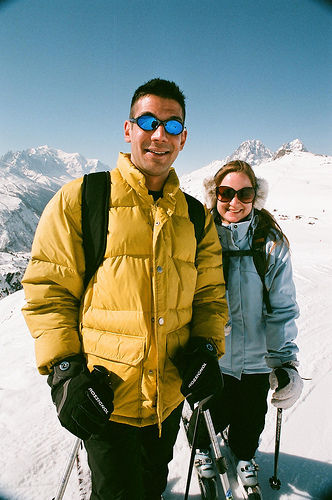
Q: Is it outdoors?
A: Yes, it is outdoors.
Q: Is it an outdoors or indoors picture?
A: It is outdoors.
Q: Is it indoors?
A: No, it is outdoors.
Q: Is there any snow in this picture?
A: Yes, there is snow.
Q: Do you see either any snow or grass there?
A: Yes, there is snow.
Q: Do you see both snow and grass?
A: No, there is snow but no grass.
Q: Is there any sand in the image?
A: No, there is no sand.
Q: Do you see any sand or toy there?
A: No, there are no sand or toys.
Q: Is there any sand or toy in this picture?
A: No, there are no sand or toys.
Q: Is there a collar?
A: Yes, there is a collar.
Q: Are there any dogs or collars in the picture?
A: Yes, there is a collar.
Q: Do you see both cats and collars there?
A: No, there is a collar but no cats.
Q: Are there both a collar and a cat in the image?
A: No, there is a collar but no cats.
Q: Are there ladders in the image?
A: No, there are no ladders.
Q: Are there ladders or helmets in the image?
A: No, there are no ladders or helmets.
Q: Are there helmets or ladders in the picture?
A: No, there are no ladders or helmets.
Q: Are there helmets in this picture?
A: No, there are no helmets.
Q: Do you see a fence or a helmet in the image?
A: No, there are no helmets or fences.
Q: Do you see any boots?
A: Yes, there are boots.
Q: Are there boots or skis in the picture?
A: Yes, there are boots.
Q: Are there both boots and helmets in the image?
A: No, there are boots but no helmets.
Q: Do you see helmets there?
A: No, there are no helmets.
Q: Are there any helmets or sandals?
A: No, there are no helmets or sandals.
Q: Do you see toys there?
A: No, there are no toys.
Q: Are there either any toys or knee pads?
A: No, there are no toys or knee pads.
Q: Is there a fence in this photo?
A: No, there are no fences.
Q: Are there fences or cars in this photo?
A: No, there are no fences or cars.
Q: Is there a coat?
A: Yes, there is a coat.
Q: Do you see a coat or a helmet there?
A: Yes, there is a coat.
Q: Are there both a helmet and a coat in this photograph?
A: No, there is a coat but no helmets.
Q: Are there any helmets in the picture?
A: No, there are no helmets.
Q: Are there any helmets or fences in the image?
A: No, there are no helmets or fences.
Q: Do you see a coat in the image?
A: Yes, there is a coat.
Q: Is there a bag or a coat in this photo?
A: Yes, there is a coat.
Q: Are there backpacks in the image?
A: Yes, there is a backpack.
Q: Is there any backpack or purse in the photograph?
A: Yes, there is a backpack.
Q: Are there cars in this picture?
A: No, there are no cars.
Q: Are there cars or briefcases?
A: No, there are no cars or briefcases.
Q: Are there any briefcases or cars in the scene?
A: No, there are no cars or briefcases.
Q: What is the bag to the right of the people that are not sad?
A: The bag is a backpack.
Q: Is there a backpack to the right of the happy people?
A: Yes, there is a backpack to the right of the people.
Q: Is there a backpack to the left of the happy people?
A: No, the backpack is to the right of the people.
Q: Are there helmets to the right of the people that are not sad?
A: No, there is a backpack to the right of the people.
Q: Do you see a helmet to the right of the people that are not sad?
A: No, there is a backpack to the right of the people.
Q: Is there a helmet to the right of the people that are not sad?
A: No, there is a backpack to the right of the people.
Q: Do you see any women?
A: Yes, there is a woman.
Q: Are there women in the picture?
A: Yes, there is a woman.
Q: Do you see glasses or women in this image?
A: Yes, there is a woman.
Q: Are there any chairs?
A: No, there are no chairs.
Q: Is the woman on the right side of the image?
A: Yes, the woman is on the right of the image.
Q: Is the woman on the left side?
A: No, the woman is on the right of the image.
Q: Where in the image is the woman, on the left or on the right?
A: The woman is on the right of the image.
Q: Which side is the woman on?
A: The woman is on the right of the image.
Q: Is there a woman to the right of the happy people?
A: Yes, there is a woman to the right of the people.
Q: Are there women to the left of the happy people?
A: No, the woman is to the right of the people.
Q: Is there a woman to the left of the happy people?
A: No, the woman is to the right of the people.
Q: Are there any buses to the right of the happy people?
A: No, there is a woman to the right of the people.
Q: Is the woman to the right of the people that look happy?
A: Yes, the woman is to the right of the people.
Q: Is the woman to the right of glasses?
A: No, the woman is to the right of the people.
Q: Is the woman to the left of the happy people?
A: No, the woman is to the right of the people.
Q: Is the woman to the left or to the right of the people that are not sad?
A: The woman is to the right of the people.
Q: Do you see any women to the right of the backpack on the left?
A: Yes, there is a woman to the right of the backpack.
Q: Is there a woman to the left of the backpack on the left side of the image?
A: No, the woman is to the right of the backpack.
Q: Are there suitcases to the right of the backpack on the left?
A: No, there is a woman to the right of the backpack.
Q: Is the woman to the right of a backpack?
A: Yes, the woman is to the right of a backpack.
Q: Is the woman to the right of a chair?
A: No, the woman is to the right of a backpack.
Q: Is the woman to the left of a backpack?
A: No, the woman is to the right of a backpack.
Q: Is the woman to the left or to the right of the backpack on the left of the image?
A: The woman is to the right of the backpack.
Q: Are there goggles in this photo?
A: Yes, there are goggles.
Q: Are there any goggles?
A: Yes, there are goggles.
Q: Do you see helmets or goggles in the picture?
A: Yes, there are goggles.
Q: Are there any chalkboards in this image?
A: No, there are no chalkboards.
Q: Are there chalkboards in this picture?
A: No, there are no chalkboards.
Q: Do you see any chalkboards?
A: No, there are no chalkboards.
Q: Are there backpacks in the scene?
A: Yes, there is a backpack.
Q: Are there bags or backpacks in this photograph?
A: Yes, there is a backpack.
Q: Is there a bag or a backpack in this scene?
A: Yes, there is a backpack.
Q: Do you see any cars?
A: No, there are no cars.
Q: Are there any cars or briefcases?
A: No, there are no cars or briefcases.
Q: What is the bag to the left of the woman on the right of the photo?
A: The bag is a backpack.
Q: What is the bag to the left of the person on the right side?
A: The bag is a backpack.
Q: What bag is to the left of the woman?
A: The bag is a backpack.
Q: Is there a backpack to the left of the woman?
A: Yes, there is a backpack to the left of the woman.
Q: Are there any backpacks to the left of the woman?
A: Yes, there is a backpack to the left of the woman.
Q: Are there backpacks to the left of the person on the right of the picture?
A: Yes, there is a backpack to the left of the woman.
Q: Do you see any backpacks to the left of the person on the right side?
A: Yes, there is a backpack to the left of the woman.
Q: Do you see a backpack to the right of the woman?
A: No, the backpack is to the left of the woman.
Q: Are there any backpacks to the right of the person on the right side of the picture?
A: No, the backpack is to the left of the woman.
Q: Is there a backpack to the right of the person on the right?
A: No, the backpack is to the left of the woman.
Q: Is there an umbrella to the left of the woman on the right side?
A: No, there is a backpack to the left of the woman.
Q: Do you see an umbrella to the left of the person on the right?
A: No, there is a backpack to the left of the woman.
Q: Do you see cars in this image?
A: No, there are no cars.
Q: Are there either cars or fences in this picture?
A: No, there are no cars or fences.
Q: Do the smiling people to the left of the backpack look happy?
A: Yes, the people are happy.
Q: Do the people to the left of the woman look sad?
A: No, the people are happy.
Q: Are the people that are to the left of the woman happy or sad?
A: The people are happy.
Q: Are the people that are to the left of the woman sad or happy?
A: The people are happy.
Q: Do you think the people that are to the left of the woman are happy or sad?
A: The people are happy.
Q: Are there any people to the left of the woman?
A: Yes, there are people to the left of the woman.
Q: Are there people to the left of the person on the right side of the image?
A: Yes, there are people to the left of the woman.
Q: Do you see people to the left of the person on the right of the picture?
A: Yes, there are people to the left of the woman.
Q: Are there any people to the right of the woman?
A: No, the people are to the left of the woman.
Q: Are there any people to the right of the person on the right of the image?
A: No, the people are to the left of the woman.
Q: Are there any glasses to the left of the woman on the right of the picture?
A: No, there are people to the left of the woman.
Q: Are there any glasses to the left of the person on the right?
A: No, there are people to the left of the woman.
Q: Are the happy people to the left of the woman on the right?
A: Yes, the people are to the left of the woman.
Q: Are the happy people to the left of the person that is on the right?
A: Yes, the people are to the left of the woman.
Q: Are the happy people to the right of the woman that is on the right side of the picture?
A: No, the people are to the left of the woman.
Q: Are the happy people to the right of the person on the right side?
A: No, the people are to the left of the woman.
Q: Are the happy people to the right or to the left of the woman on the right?
A: The people are to the left of the woman.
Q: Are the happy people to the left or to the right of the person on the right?
A: The people are to the left of the woman.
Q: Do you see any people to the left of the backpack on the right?
A: Yes, there are people to the left of the backpack.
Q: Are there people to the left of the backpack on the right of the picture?
A: Yes, there are people to the left of the backpack.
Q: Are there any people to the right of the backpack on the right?
A: No, the people are to the left of the backpack.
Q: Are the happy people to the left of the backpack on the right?
A: Yes, the people are to the left of the backpack.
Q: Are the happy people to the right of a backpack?
A: No, the people are to the left of a backpack.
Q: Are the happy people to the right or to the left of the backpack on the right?
A: The people are to the left of the backpack.